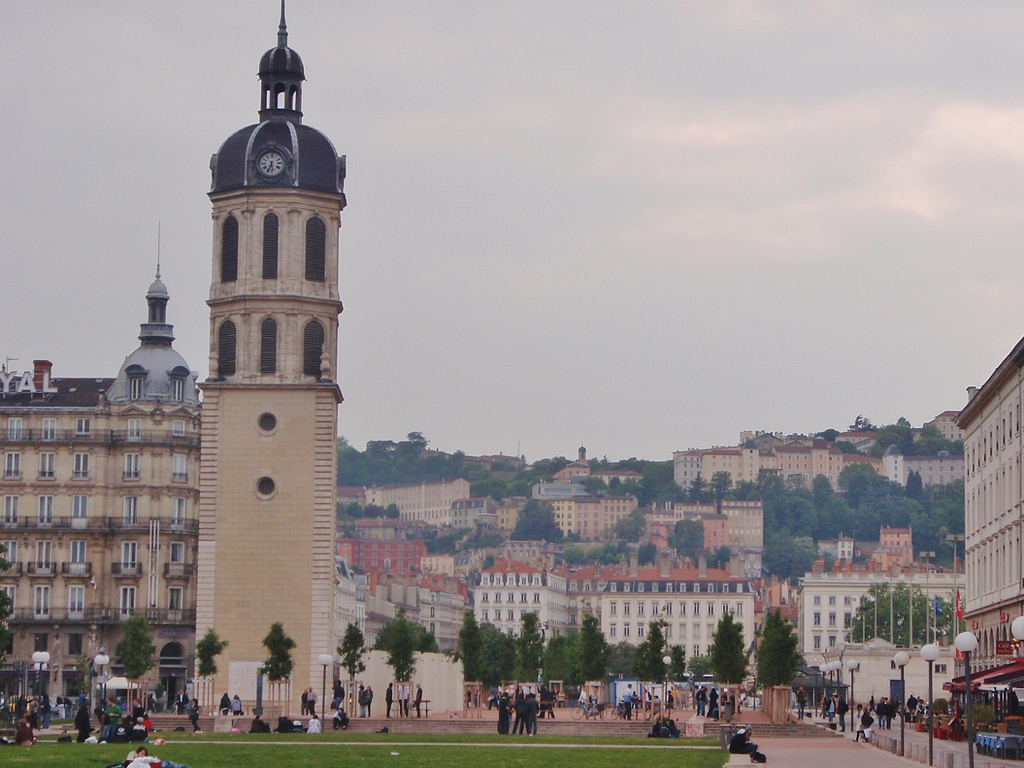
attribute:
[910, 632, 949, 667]
globe — white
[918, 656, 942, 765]
utility pole — black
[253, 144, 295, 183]
clock — white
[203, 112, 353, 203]
dome roof — black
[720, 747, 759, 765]
curb — concrete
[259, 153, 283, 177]
clock face — white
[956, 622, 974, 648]
light ball — round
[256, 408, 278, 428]
circle — small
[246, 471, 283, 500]
circle — small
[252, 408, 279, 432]
circle — black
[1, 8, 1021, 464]
sky — cloudy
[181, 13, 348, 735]
tower — huge, stone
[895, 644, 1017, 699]
light — white, dome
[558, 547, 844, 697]
building — dark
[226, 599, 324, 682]
leaves — green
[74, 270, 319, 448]
dome — grey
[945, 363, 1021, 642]
building — old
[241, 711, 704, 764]
grass — green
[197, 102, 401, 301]
roof — domed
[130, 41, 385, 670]
tower — tall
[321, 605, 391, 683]
tree — thin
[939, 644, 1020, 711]
awning — red